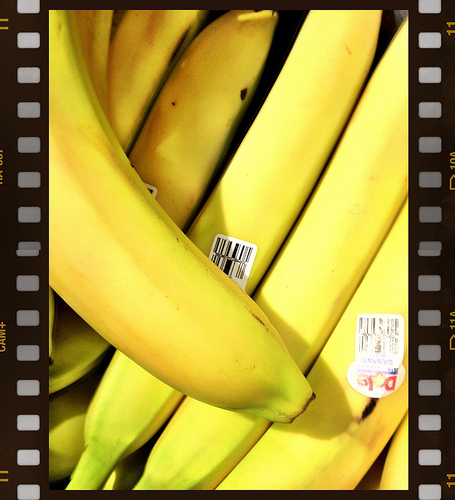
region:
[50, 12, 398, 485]
bunch of yellow bananas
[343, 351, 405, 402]
white oval DOLE sticker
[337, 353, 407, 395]
DOLE logo in red lettering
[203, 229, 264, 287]
white sticker with a black bar code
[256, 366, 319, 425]
green and brown end of banana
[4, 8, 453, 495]
photograph with film edging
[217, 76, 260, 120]
brown spot on banana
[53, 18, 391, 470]
bright yellow bananas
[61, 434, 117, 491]
stem of banana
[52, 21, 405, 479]
photograph of yellow bananas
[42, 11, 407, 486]
A bundle of bananas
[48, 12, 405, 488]
The bananas are yellow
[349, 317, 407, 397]
White sticker on bananas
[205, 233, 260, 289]
White and black barcode sticker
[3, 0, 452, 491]
Movie reel border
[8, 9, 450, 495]
Movie reel border is grey and black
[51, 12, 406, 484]
The bananas are large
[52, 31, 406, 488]
The bananas are long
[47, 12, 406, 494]
The bananas are piled on top of each other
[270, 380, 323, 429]
The end of the banana is brown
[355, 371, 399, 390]
A Dole logo on the banana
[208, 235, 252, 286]
A sticker on the banana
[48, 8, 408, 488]
A bunch of bananas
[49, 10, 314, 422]
The banana is yellow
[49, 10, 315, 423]
A banana on top of another banana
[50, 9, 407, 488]
The bananas are Dole brand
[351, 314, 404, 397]
A Dole sticker on the banana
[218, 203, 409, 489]
The banana has a sticker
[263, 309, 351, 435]
A shadow on the banana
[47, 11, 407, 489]
Yellow fruits in a bunch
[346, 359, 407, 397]
Oblong, upside down Dole sticker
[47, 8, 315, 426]
Banana lying across other bananas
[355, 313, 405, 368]
Sticker with UPC code partially covering Dole sticker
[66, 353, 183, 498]
Green top of a banana with a UPC sticker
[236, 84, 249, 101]
Small brown spot on the corner of a banana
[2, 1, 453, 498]
Brown frame with white rectangles surrounding a picture of bananas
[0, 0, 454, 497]
Film slide of a group of yellow bananas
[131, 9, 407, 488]
Yellow banana between two bananas with UPC stickers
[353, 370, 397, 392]
Red and yellow Dole logo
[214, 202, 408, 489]
Bruised banana with a Dole sticker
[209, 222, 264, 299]
tag on banana is reader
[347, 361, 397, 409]
name of banana upside down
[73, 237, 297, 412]
color of banana is yellow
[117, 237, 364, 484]
more than one banana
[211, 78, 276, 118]
brown mark on banana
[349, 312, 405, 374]
paper with code on it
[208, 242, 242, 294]
ups code on banana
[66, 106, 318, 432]
banana is covering other bananas